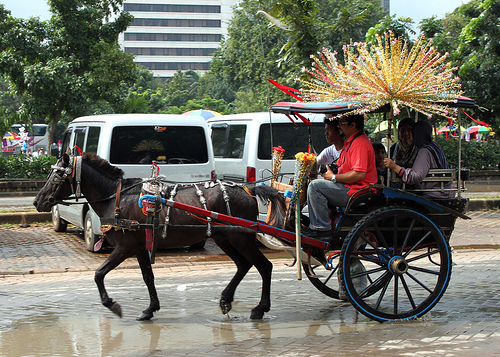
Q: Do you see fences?
A: No, there are no fences.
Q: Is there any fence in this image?
A: No, there are no fences.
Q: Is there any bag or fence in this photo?
A: No, there are no fences or bags.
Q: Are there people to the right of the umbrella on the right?
A: No, the person is to the left of the umbrella.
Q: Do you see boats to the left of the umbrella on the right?
A: No, there is a person to the left of the umbrella.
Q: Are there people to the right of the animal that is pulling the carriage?
A: Yes, there is a person to the right of the horse.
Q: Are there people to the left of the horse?
A: No, the person is to the right of the horse.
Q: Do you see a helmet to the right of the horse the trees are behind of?
A: No, there is a person to the right of the horse.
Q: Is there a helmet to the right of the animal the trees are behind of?
A: No, there is a person to the right of the horse.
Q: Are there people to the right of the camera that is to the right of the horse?
A: Yes, there is a person to the right of the camera.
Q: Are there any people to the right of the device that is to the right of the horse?
A: Yes, there is a person to the right of the camera.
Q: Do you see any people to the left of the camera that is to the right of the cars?
A: No, the person is to the right of the camera.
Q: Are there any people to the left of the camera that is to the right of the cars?
A: No, the person is to the right of the camera.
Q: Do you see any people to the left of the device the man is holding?
A: No, the person is to the right of the camera.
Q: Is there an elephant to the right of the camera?
A: No, there is a person to the right of the camera.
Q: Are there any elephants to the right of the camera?
A: No, there is a person to the right of the camera.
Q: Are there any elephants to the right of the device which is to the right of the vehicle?
A: No, there is a person to the right of the camera.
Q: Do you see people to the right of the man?
A: Yes, there is a person to the right of the man.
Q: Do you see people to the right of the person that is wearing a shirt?
A: Yes, there is a person to the right of the man.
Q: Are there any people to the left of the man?
A: No, the person is to the right of the man.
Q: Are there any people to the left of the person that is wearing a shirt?
A: No, the person is to the right of the man.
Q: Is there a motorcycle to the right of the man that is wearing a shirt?
A: No, there is a person to the right of the man.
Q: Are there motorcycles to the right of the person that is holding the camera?
A: No, there is a person to the right of the man.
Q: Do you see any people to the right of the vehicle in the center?
A: Yes, there is a person to the right of the vehicle.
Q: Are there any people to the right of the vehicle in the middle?
A: Yes, there is a person to the right of the vehicle.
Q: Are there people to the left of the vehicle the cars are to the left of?
A: No, the person is to the right of the vehicle.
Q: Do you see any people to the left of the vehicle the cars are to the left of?
A: No, the person is to the right of the vehicle.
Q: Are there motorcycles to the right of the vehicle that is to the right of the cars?
A: No, there is a person to the right of the vehicle.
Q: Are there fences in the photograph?
A: No, there are no fences.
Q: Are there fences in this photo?
A: No, there are no fences.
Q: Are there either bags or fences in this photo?
A: No, there are no fences or bags.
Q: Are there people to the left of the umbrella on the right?
A: Yes, there are people to the left of the umbrella.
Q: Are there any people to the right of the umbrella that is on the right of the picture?
A: No, the people are to the left of the umbrella.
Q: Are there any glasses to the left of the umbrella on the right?
A: No, there are people to the left of the umbrella.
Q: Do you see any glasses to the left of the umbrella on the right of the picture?
A: No, there are people to the left of the umbrella.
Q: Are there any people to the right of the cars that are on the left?
A: Yes, there are people to the right of the cars.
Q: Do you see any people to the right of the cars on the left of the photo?
A: Yes, there are people to the right of the cars.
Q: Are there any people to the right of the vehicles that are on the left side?
A: Yes, there are people to the right of the cars.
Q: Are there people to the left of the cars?
A: No, the people are to the right of the cars.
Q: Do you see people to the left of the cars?
A: No, the people are to the right of the cars.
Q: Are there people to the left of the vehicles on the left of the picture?
A: No, the people are to the right of the cars.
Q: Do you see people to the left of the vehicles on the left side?
A: No, the people are to the right of the cars.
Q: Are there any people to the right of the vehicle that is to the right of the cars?
A: Yes, there are people to the right of the vehicle.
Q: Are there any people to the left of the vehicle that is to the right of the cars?
A: No, the people are to the right of the vehicle.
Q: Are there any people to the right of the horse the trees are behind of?
A: Yes, there are people to the right of the horse.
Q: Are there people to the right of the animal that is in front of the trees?
A: Yes, there are people to the right of the horse.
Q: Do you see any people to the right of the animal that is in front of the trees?
A: Yes, there are people to the right of the horse.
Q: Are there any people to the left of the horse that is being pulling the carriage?
A: No, the people are to the right of the horse.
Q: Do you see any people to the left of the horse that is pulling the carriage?
A: No, the people are to the right of the horse.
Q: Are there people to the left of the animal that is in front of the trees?
A: No, the people are to the right of the horse.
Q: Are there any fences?
A: No, there are no fences.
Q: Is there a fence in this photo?
A: No, there are no fences.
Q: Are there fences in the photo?
A: No, there are no fences.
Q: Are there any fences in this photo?
A: No, there are no fences.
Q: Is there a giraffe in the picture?
A: No, there are no giraffes.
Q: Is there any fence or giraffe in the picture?
A: No, there are no giraffes or fences.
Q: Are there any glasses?
A: No, there are no glasses.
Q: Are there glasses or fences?
A: No, there are no glasses or fences.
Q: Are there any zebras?
A: No, there are no zebras.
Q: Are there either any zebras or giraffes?
A: No, there are no zebras or giraffes.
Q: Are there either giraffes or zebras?
A: No, there are no zebras or giraffes.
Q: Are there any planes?
A: No, there are no planes.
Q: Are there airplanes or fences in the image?
A: No, there are no airplanes or fences.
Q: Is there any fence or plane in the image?
A: No, there are no airplanes or fences.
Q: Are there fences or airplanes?
A: No, there are no airplanes or fences.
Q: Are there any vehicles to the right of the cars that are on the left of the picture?
A: Yes, there is a vehicle to the right of the cars.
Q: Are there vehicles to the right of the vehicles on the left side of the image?
A: Yes, there is a vehicle to the right of the cars.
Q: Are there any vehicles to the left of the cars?
A: No, the vehicle is to the right of the cars.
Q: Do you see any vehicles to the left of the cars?
A: No, the vehicle is to the right of the cars.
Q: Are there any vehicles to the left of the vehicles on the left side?
A: No, the vehicle is to the right of the cars.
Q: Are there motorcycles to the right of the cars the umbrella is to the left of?
A: No, there is a vehicle to the right of the cars.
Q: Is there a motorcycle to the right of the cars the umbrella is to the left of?
A: No, there is a vehicle to the right of the cars.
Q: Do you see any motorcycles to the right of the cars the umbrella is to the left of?
A: No, there is a vehicle to the right of the cars.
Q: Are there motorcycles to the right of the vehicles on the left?
A: No, there is a vehicle to the right of the cars.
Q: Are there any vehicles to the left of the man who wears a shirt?
A: Yes, there is a vehicle to the left of the man.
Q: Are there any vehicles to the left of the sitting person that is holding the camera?
A: Yes, there is a vehicle to the left of the man.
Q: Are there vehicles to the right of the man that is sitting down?
A: No, the vehicle is to the left of the man.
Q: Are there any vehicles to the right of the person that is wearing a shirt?
A: No, the vehicle is to the left of the man.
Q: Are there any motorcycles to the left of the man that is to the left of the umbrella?
A: No, there is a vehicle to the left of the man.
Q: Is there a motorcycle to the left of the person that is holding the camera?
A: No, there is a vehicle to the left of the man.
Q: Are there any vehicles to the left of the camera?
A: Yes, there is a vehicle to the left of the camera.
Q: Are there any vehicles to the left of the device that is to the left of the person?
A: Yes, there is a vehicle to the left of the camera.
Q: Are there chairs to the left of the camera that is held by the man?
A: No, there is a vehicle to the left of the camera.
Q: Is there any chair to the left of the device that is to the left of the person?
A: No, there is a vehicle to the left of the camera.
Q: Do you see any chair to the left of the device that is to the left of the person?
A: No, there is a vehicle to the left of the camera.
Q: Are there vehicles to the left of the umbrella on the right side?
A: Yes, there is a vehicle to the left of the umbrella.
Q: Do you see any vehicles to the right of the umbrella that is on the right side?
A: No, the vehicle is to the left of the umbrella.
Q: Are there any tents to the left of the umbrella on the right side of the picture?
A: No, there is a vehicle to the left of the umbrella.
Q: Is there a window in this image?
A: Yes, there is a window.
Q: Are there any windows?
A: Yes, there is a window.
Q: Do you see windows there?
A: Yes, there is a window.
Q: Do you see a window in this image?
A: Yes, there is a window.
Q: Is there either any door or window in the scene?
A: Yes, there is a window.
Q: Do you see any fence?
A: No, there are no fences.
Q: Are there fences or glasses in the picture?
A: No, there are no fences or glasses.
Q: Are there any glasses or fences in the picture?
A: No, there are no fences or glasses.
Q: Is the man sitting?
A: Yes, the man is sitting.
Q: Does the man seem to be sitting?
A: Yes, the man is sitting.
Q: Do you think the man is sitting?
A: Yes, the man is sitting.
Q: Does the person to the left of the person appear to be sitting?
A: Yes, the man is sitting.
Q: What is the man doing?
A: The man is sitting.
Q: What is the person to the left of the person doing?
A: The man is sitting.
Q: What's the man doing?
A: The man is sitting.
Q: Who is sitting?
A: The man is sitting.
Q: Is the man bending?
A: No, the man is sitting.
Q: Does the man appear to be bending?
A: No, the man is sitting.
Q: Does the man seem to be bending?
A: No, the man is sitting.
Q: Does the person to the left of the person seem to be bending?
A: No, the man is sitting.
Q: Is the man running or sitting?
A: The man is sitting.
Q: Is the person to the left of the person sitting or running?
A: The man is sitting.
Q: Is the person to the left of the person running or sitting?
A: The man is sitting.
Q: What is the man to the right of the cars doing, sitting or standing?
A: The man is sitting.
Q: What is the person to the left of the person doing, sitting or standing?
A: The man is sitting.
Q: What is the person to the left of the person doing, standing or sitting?
A: The man is sitting.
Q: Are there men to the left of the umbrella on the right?
A: Yes, there is a man to the left of the umbrella.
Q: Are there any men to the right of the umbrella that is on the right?
A: No, the man is to the left of the umbrella.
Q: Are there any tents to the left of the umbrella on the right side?
A: No, there is a man to the left of the umbrella.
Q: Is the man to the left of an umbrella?
A: Yes, the man is to the left of an umbrella.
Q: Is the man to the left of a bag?
A: No, the man is to the left of an umbrella.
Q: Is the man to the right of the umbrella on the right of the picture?
A: No, the man is to the left of the umbrella.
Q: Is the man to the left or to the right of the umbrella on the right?
A: The man is to the left of the umbrella.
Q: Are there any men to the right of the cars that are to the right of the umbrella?
A: Yes, there is a man to the right of the cars.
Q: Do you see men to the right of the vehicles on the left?
A: Yes, there is a man to the right of the cars.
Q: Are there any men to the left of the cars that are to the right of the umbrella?
A: No, the man is to the right of the cars.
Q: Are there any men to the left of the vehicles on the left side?
A: No, the man is to the right of the cars.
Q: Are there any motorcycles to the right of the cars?
A: No, there is a man to the right of the cars.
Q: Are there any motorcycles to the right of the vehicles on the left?
A: No, there is a man to the right of the cars.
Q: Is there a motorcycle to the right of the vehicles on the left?
A: No, there is a man to the right of the cars.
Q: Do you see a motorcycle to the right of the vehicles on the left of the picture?
A: No, there is a man to the right of the cars.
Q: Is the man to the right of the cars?
A: Yes, the man is to the right of the cars.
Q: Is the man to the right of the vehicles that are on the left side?
A: Yes, the man is to the right of the cars.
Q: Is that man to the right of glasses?
A: No, the man is to the right of the cars.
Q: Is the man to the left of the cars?
A: No, the man is to the right of the cars.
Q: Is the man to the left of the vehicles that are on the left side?
A: No, the man is to the right of the cars.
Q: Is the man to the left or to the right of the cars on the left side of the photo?
A: The man is to the right of the cars.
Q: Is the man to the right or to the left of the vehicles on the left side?
A: The man is to the right of the cars.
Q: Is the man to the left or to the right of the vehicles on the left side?
A: The man is to the right of the cars.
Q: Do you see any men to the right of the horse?
A: Yes, there is a man to the right of the horse.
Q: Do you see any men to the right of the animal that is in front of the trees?
A: Yes, there is a man to the right of the horse.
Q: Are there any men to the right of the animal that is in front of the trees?
A: Yes, there is a man to the right of the horse.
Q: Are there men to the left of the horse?
A: No, the man is to the right of the horse.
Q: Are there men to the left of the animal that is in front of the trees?
A: No, the man is to the right of the horse.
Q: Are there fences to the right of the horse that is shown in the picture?
A: No, there is a man to the right of the horse.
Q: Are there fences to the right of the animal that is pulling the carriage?
A: No, there is a man to the right of the horse.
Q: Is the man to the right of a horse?
A: Yes, the man is to the right of a horse.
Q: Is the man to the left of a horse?
A: No, the man is to the right of a horse.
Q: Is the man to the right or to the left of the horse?
A: The man is to the right of the horse.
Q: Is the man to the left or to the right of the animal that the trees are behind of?
A: The man is to the right of the horse.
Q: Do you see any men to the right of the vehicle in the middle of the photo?
A: Yes, there is a man to the right of the vehicle.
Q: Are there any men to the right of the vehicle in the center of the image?
A: Yes, there is a man to the right of the vehicle.